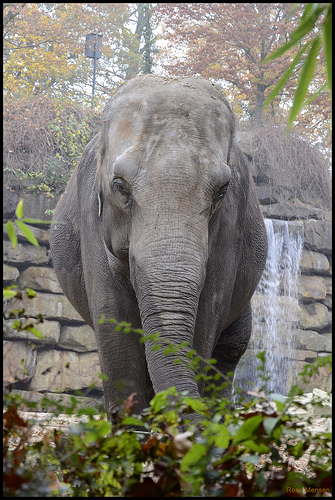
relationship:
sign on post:
[84, 34, 101, 58] [91, 42, 94, 109]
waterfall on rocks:
[232, 218, 305, 405] [232, 164, 332, 404]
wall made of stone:
[2, 174, 334, 418] [278, 244, 329, 274]